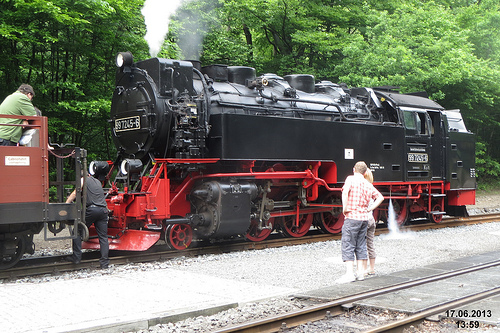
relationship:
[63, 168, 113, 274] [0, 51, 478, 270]
man checking out train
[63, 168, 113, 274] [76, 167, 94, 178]
man wearing baseball hat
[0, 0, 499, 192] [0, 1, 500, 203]
forest in background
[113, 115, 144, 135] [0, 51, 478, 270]
numbers on back of train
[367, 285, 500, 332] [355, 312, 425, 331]
rail has a part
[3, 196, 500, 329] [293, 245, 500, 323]
ground has a part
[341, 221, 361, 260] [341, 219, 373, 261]
part of pants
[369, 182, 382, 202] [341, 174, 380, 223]
part of a shirt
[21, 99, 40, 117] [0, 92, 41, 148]
part of a shirt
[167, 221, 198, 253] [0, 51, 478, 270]
wheel of a train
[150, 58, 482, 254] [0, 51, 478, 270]
side of a train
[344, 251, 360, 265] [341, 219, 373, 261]
edge of pants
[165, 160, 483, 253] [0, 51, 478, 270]
edge of a train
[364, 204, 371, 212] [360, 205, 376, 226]
hand on hip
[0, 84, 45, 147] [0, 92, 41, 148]
man wearing shirt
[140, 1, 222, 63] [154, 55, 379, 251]
steam coming out of engine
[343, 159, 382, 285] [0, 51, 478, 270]
couple standing by train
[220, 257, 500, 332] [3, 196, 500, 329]
tracks on ground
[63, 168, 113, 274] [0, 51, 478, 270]
man by a train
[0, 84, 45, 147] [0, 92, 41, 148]
man wearing green shirt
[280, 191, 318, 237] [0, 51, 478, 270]
wheel on a train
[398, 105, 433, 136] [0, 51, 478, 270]
window on a train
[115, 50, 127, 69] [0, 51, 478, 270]
light on a train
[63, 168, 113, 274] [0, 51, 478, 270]
man looking at train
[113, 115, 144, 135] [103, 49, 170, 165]
numbers at end of train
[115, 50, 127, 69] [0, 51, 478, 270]
light on top of train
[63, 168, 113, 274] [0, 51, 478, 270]
man inspecting train